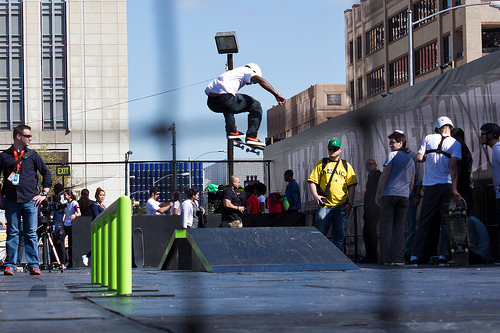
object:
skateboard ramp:
[158, 226, 362, 273]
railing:
[88, 195, 134, 298]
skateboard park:
[2, 55, 499, 332]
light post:
[407, 1, 490, 90]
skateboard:
[447, 190, 471, 268]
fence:
[6, 154, 276, 275]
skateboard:
[134, 227, 147, 268]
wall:
[132, 212, 186, 269]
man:
[308, 139, 360, 252]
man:
[1, 122, 54, 276]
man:
[373, 130, 417, 267]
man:
[362, 158, 385, 265]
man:
[477, 121, 500, 265]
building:
[265, 1, 500, 257]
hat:
[327, 139, 342, 148]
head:
[327, 139, 343, 162]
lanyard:
[13, 150, 24, 174]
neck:
[9, 143, 29, 153]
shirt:
[307, 157, 362, 207]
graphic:
[320, 168, 348, 178]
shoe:
[246, 135, 267, 147]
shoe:
[226, 129, 246, 139]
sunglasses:
[328, 147, 339, 152]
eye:
[328, 148, 332, 151]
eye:
[334, 148, 338, 151]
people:
[220, 174, 247, 228]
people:
[401, 116, 463, 268]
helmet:
[245, 63, 262, 78]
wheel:
[448, 211, 454, 220]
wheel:
[462, 210, 467, 217]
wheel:
[450, 248, 456, 254]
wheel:
[465, 248, 470, 255]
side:
[157, 228, 189, 273]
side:
[187, 226, 360, 272]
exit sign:
[55, 165, 72, 175]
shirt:
[204, 65, 257, 98]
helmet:
[432, 116, 454, 131]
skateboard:
[230, 136, 267, 154]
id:
[7, 172, 20, 186]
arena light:
[213, 29, 241, 56]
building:
[0, 1, 130, 207]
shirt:
[0, 145, 55, 206]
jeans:
[2, 199, 42, 270]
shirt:
[418, 132, 461, 188]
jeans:
[206, 91, 263, 138]